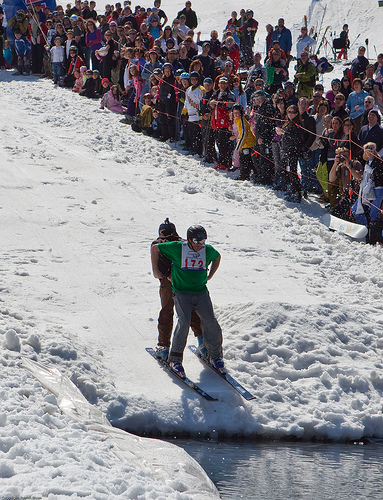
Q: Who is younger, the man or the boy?
A: The boy is younger than the man.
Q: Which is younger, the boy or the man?
A: The boy is younger than the man.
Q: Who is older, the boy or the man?
A: The man is older than the boy.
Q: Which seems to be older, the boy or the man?
A: The man is older than the boy.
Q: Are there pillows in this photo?
A: No, there are no pillows.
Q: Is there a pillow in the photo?
A: No, there are no pillows.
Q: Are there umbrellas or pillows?
A: No, there are no pillows or umbrellas.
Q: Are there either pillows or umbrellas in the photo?
A: No, there are no pillows or umbrellas.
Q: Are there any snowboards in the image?
A: Yes, there is a snowboard.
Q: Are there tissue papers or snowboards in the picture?
A: Yes, there is a snowboard.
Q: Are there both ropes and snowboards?
A: Yes, there are both a snowboard and a rope.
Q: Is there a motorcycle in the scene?
A: No, there are no motorcycles.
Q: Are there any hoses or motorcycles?
A: No, there are no motorcycles or hoses.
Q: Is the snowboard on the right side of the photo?
A: Yes, the snowboard is on the right of the image.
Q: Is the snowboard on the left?
A: No, the snowboard is on the right of the image.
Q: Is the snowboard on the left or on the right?
A: The snowboard is on the right of the image.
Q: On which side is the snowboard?
A: The snowboard is on the right of the image.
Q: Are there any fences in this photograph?
A: No, there are no fences.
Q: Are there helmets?
A: Yes, there is a helmet.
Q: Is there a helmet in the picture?
A: Yes, there is a helmet.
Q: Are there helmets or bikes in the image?
A: Yes, there is a helmet.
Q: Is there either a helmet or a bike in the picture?
A: Yes, there is a helmet.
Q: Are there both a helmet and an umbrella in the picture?
A: No, there is a helmet but no umbrellas.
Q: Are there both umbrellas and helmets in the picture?
A: No, there is a helmet but no umbrellas.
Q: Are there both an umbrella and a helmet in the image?
A: No, there is a helmet but no umbrellas.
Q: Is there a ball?
A: No, there are no balls.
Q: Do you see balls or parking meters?
A: No, there are no balls or parking meters.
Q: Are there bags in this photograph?
A: No, there are no bags.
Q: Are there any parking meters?
A: No, there are no parking meters.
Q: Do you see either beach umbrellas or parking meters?
A: No, there are no parking meters or beach umbrellas.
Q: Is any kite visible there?
A: No, there are no kites.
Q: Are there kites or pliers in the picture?
A: No, there are no kites or pliers.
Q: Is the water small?
A: Yes, the water is small.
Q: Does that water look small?
A: Yes, the water is small.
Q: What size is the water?
A: The water is small.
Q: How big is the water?
A: The water is small.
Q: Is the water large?
A: No, the water is small.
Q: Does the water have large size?
A: No, the water is small.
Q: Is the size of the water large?
A: No, the water is small.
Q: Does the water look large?
A: No, the water is small.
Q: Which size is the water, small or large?
A: The water is small.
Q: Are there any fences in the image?
A: No, there are no fences.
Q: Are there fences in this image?
A: No, there are no fences.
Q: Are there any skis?
A: Yes, there are skis.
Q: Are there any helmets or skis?
A: Yes, there are skis.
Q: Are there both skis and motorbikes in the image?
A: No, there are skis but no motorcycles.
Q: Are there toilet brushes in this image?
A: No, there are no toilet brushes.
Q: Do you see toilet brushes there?
A: No, there are no toilet brushes.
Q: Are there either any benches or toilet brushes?
A: No, there are no toilet brushes or benches.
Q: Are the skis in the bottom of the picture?
A: Yes, the skis are in the bottom of the image.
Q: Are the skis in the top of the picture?
A: No, the skis are in the bottom of the image.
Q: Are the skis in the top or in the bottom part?
A: The skis are in the bottom of the image.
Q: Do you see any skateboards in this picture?
A: No, there are no skateboards.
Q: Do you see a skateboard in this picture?
A: No, there are no skateboards.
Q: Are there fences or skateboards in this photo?
A: No, there are no skateboards or fences.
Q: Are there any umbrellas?
A: No, there are no umbrellas.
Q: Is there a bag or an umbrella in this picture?
A: No, there are no umbrellas or bags.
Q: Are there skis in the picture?
A: Yes, there are skis.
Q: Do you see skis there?
A: Yes, there are skis.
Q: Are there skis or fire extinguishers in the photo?
A: Yes, there are skis.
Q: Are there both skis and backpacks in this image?
A: No, there are skis but no backpacks.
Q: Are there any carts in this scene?
A: No, there are no carts.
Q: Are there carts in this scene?
A: No, there are no carts.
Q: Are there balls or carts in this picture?
A: No, there are no carts or balls.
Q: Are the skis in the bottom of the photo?
A: Yes, the skis are in the bottom of the image.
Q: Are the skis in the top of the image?
A: No, the skis are in the bottom of the image.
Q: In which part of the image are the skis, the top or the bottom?
A: The skis are in the bottom of the image.